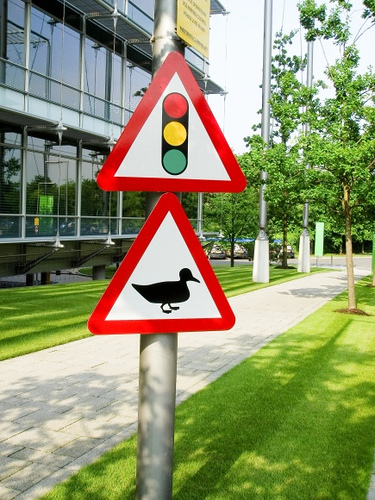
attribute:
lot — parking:
[197, 215, 370, 265]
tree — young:
[242, 110, 360, 229]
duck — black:
[130, 268, 200, 313]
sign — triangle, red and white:
[88, 191, 234, 332]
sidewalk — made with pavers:
[3, 265, 369, 496]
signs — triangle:
[46, 29, 327, 480]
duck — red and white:
[128, 264, 201, 309]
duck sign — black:
[83, 192, 238, 335]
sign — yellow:
[178, 4, 216, 66]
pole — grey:
[128, 335, 182, 495]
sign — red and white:
[94, 199, 234, 331]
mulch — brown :
[333, 305, 369, 316]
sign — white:
[75, 190, 247, 366]